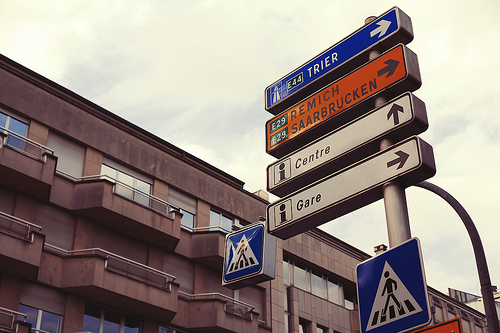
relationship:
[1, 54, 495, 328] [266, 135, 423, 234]
building behind sign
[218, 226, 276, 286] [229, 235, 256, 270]
sign says walk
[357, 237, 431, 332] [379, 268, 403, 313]
sign says walk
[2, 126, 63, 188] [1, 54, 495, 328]
balcony on building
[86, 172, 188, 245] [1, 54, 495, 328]
balcony on building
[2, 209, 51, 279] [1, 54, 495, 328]
balcony on building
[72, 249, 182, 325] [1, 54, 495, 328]
balcony on building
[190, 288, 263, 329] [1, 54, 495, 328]
balcony on building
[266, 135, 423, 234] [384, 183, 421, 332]
sign on pole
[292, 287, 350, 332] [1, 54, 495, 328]
tile on building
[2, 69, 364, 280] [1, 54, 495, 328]
tile on building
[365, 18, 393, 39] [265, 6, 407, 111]
arrow on sign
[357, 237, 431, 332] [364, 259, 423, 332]
sign has triangle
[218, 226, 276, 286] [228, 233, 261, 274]
sign has triangle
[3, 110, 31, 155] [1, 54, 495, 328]
window on building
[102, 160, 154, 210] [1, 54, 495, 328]
window on building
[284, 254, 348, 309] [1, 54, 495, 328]
window on building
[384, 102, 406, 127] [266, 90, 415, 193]
arrow on sign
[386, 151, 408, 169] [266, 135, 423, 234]
arrow on sign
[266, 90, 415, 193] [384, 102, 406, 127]
sign has arrow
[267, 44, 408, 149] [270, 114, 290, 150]
sign says e29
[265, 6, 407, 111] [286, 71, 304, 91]
sign says e44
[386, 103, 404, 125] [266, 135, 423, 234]
arrow on sign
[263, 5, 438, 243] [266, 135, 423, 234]
stack of sign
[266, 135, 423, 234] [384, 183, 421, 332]
sign attatched to pole